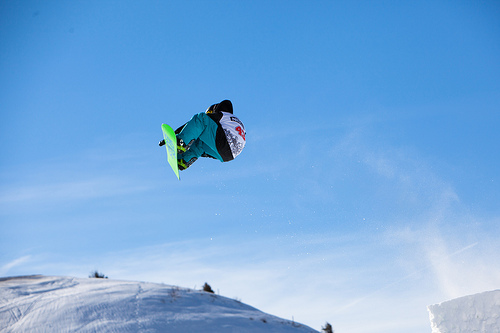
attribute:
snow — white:
[0, 273, 327, 332]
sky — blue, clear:
[1, 1, 499, 302]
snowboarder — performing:
[162, 99, 246, 179]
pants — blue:
[174, 111, 226, 168]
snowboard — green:
[158, 125, 184, 178]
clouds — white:
[411, 227, 468, 282]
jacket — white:
[213, 109, 248, 161]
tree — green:
[198, 283, 216, 294]